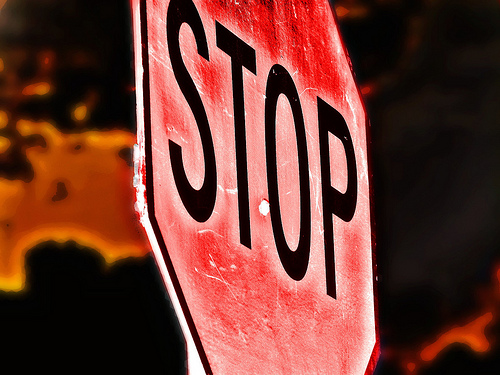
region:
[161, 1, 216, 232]
black letter S on a stop sign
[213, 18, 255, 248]
black letter T on a stop sign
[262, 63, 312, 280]
black letter O on a stop sign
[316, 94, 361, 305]
black letter P on a stop sign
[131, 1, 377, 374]
a bright red stop sign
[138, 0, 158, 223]
black line on the perimeter of a stop sign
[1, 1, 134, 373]
black and orange coloring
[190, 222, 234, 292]
scratches on a stop sign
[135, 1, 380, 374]
a stop sign with a lot of scratches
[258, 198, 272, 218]
large hole in a stop sign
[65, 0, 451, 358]
stop sign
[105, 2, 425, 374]
red and black stop sign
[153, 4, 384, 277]
large thick letters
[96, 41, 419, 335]
red sign with black border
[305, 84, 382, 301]
black letter p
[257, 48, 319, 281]
black letter o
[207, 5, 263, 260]
black letter t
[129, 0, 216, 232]
black letter s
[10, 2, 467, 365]
neon colored stop sign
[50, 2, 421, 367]
street sign to signal people to stop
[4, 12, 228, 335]
red orange and black background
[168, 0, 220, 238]
letter s on red stop sign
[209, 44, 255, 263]
letter t on red stop sign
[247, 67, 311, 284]
letter o on red stop sign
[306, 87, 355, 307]
letter p on red stop sign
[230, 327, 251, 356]
white scratch on stop sign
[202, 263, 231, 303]
white scratch on stop sign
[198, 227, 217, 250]
white scratch on stop sign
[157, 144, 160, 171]
white scratch on stop sign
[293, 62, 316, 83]
white scratch on stop sign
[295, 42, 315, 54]
white scratch on stop sign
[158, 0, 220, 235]
letter s on stop sign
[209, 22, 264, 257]
letter t on stop sign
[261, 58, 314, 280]
letter o on stop sign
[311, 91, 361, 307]
letter p on stop sign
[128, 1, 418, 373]
red stop sign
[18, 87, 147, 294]
background of stop sign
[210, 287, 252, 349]
scratches on stop sign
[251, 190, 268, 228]
scratches on stop sign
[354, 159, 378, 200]
scratch on stop sign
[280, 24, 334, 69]
scratch on stop sign